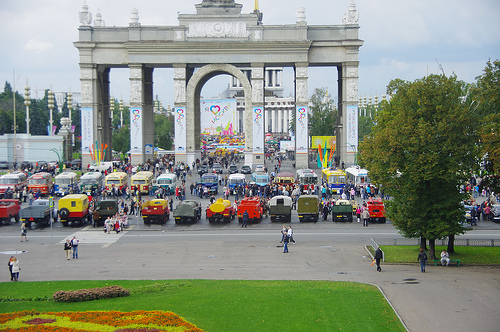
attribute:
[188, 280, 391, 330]
grass — many green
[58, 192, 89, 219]
car — red , yellow 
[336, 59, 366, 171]
column — monument 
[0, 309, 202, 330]
grass — orange, yellow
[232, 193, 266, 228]
car — red, vehicle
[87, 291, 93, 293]
flower — pretty, pink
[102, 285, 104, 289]
flower — pretty, pink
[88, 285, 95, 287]
flower — pretty, pink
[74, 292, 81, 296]
flower — pretty, pink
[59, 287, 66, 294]
flower — pretty, pink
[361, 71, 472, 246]
tree — green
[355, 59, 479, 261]
tree — giant 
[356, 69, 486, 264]
tree — leafy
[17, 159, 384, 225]
people — lot 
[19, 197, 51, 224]
bed truck — older, grey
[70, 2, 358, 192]
monument — arc 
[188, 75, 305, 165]
banner — blue, green, yellow, pink, purple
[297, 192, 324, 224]
vehicle — many, colors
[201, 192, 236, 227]
truck — red, yellow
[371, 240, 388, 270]
person — walking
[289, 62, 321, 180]
column — monument 